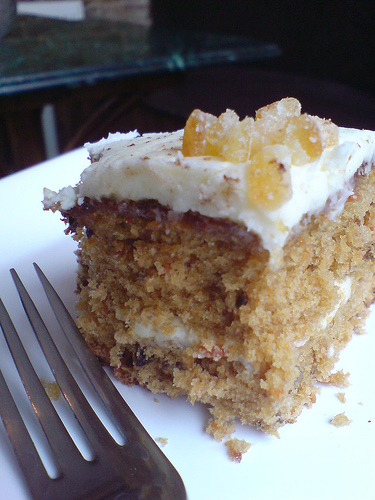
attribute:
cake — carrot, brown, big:
[78, 116, 374, 387]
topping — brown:
[246, 160, 289, 209]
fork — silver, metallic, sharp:
[2, 261, 75, 483]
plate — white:
[266, 449, 354, 496]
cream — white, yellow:
[347, 129, 374, 154]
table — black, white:
[47, 23, 132, 52]